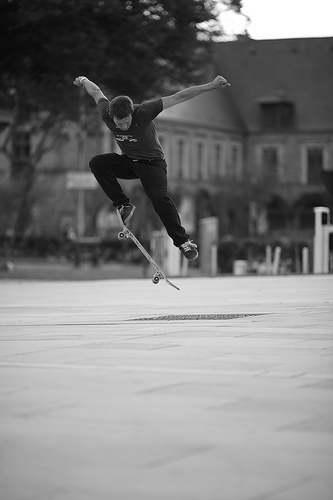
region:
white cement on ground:
[170, 380, 214, 400]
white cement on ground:
[152, 401, 181, 427]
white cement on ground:
[200, 423, 244, 453]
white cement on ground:
[271, 410, 300, 457]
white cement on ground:
[272, 343, 315, 399]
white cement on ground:
[205, 358, 238, 379]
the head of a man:
[99, 78, 164, 148]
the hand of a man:
[197, 70, 231, 108]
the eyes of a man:
[109, 99, 158, 144]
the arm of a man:
[137, 49, 240, 139]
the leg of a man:
[87, 139, 168, 215]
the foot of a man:
[108, 196, 133, 241]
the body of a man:
[96, 64, 164, 179]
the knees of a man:
[83, 145, 121, 199]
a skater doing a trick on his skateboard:
[73, 76, 227, 291]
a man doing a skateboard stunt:
[63, 68, 231, 297]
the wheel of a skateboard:
[115, 227, 128, 243]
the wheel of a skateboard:
[147, 270, 161, 287]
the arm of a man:
[147, 74, 232, 118]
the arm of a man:
[72, 71, 111, 114]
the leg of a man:
[142, 169, 191, 246]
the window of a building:
[254, 143, 287, 186]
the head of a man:
[107, 91, 143, 136]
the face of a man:
[112, 118, 135, 135]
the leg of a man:
[91, 149, 132, 207]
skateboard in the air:
[109, 204, 182, 299]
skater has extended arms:
[60, 58, 258, 199]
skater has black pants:
[66, 52, 234, 278]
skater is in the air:
[63, 56, 237, 271]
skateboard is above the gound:
[104, 207, 199, 331]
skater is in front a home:
[2, 13, 331, 287]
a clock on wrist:
[75, 70, 91, 88]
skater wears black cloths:
[62, 58, 237, 272]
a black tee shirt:
[88, 92, 170, 170]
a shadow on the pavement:
[137, 308, 259, 322]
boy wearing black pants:
[69, 72, 239, 297]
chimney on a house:
[249, 90, 302, 134]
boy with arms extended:
[70, 70, 235, 294]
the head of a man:
[102, 99, 139, 132]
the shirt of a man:
[97, 107, 166, 163]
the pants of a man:
[89, 145, 185, 252]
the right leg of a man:
[84, 148, 131, 203]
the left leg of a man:
[132, 168, 196, 242]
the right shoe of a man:
[110, 199, 133, 220]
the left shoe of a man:
[160, 237, 197, 264]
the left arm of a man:
[141, 91, 242, 117]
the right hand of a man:
[60, 66, 97, 92]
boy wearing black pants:
[85, 145, 184, 238]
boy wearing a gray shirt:
[82, 100, 158, 160]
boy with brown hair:
[104, 92, 134, 120]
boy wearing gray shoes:
[174, 238, 200, 259]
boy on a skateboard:
[112, 205, 205, 289]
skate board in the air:
[110, 207, 184, 295]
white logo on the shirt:
[110, 130, 144, 149]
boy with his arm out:
[60, 61, 230, 128]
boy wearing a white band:
[76, 75, 89, 85]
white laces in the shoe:
[175, 236, 196, 253]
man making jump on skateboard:
[70, 69, 232, 264]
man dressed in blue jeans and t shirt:
[70, 72, 231, 260]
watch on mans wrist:
[78, 75, 87, 84]